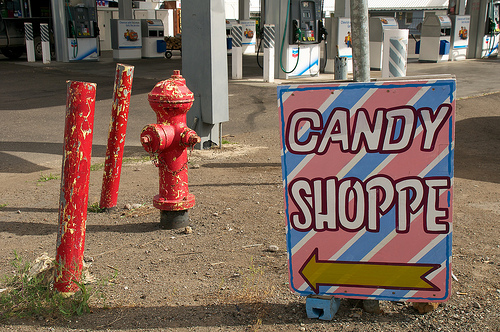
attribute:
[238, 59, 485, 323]
sign —  pink,  blue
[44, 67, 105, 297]
pole — metal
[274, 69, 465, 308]
sign — pink, white, light blue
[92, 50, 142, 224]
pole — faded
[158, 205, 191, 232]
base —  black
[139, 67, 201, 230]
hydrant —  chipped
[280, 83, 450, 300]
stripe — Pink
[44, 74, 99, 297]
pole — red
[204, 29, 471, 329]
sign — blue, pink, white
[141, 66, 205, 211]
fire hydrant — red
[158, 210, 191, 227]
post — black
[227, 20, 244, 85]
pole — white, striped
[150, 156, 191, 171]
chain — Red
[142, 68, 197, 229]
hydrant — fire hydrant, red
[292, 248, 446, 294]
arrow —  tan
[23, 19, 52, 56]
poles — black, white, striped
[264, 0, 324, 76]
gas pump — black, white, colorful, designs, Green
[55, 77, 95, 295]
pole — red, faded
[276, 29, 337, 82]
gas pump — designs, white, black, colorful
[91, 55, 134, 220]
pole — chipped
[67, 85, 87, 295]
pole —  metal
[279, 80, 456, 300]
sign — pink, blue, white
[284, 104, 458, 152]
white letters —  white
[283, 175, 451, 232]
white letters —  white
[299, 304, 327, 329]
brick — blue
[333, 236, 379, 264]
stripes —  white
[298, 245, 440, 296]
arrow — yellow, brown, Green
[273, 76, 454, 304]
stripe — blue